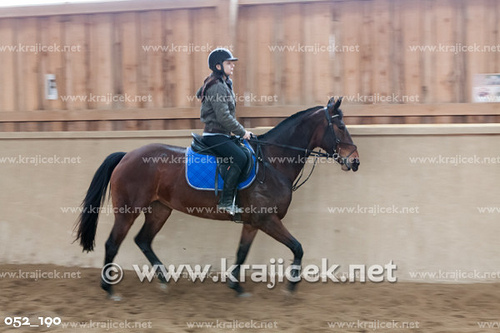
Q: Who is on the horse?
A: Rider.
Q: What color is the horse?
A: Brown.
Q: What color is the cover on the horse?
A: Blue.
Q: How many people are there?
A: One.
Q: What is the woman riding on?
A: Horse.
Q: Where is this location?
A: Arena.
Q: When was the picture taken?
A: Daytime.